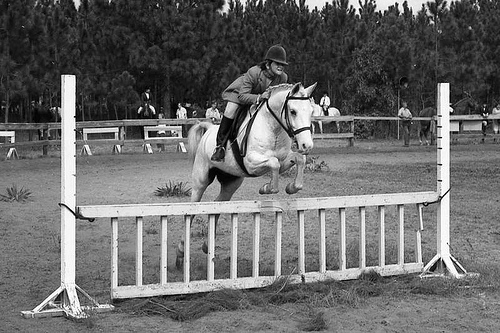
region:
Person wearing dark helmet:
[256, 39, 313, 103]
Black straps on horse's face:
[261, 70, 342, 197]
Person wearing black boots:
[203, 110, 265, 169]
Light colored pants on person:
[213, 95, 265, 155]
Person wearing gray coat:
[212, 70, 267, 93]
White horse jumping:
[118, 146, 310, 208]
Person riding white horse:
[183, 71, 301, 143]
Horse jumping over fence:
[106, 112, 400, 270]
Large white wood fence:
[23, 133, 496, 243]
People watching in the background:
[150, 90, 482, 148]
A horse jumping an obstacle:
[145, 39, 356, 268]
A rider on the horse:
[188, 43, 318, 165]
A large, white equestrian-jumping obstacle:
[22, 60, 474, 318]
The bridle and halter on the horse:
[246, 72, 329, 160]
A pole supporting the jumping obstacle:
[16, 61, 127, 328]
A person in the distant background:
[391, 87, 417, 155]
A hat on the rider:
[259, 40, 298, 80]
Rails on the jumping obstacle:
[72, 182, 442, 304]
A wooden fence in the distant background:
[0, 107, 497, 152]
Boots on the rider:
[204, 92, 242, 172]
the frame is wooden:
[52, 187, 472, 282]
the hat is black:
[250, 43, 299, 73]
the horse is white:
[193, 124, 355, 180]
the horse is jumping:
[236, 114, 327, 202]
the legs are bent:
[253, 151, 328, 183]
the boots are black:
[205, 118, 234, 160]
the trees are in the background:
[103, 58, 484, 63]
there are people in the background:
[133, 103, 204, 133]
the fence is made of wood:
[93, 114, 178, 166]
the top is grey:
[219, 61, 276, 106]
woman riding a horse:
[178, 35, 318, 196]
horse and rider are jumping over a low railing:
[31, 41, 481, 296]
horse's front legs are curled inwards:
[243, 145, 329, 205]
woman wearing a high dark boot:
[193, 105, 248, 167]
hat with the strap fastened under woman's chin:
[250, 38, 295, 78]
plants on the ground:
[2, 175, 193, 205]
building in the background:
[423, 90, 498, 150]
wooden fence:
[3, 110, 490, 155]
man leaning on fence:
[387, 85, 428, 155]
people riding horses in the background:
[116, 79, 348, 146]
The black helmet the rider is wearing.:
[266, 44, 288, 64]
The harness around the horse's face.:
[279, 106, 315, 138]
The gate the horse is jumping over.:
[81, 191, 436, 292]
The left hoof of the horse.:
[261, 176, 286, 197]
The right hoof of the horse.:
[286, 173, 299, 190]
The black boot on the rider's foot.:
[211, 112, 229, 167]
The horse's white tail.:
[182, 121, 209, 151]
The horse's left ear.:
[287, 78, 303, 99]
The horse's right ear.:
[305, 80, 318, 98]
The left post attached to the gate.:
[19, 73, 112, 329]